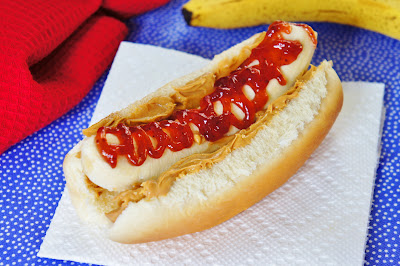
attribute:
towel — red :
[7, 8, 75, 109]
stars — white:
[1, 1, 395, 264]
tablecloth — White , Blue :
[7, 1, 397, 262]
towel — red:
[0, 12, 88, 101]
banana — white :
[165, 0, 369, 44]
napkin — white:
[33, 38, 394, 264]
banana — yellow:
[181, 0, 398, 41]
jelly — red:
[142, 75, 283, 155]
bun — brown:
[150, 149, 334, 199]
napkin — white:
[306, 68, 390, 257]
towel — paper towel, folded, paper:
[37, 34, 386, 264]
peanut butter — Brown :
[78, 31, 320, 217]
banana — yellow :
[56, 47, 330, 198]